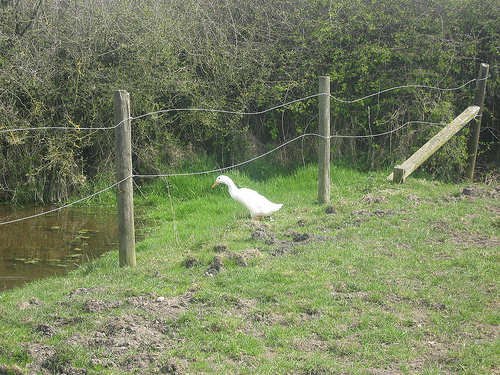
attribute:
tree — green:
[311, 7, 385, 98]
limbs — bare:
[73, 25, 151, 78]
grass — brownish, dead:
[74, 300, 194, 372]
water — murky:
[2, 204, 148, 295]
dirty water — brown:
[0, 194, 135, 294]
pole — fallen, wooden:
[387, 102, 479, 177]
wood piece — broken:
[384, 99, 481, 186]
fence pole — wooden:
[102, 81, 145, 272]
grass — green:
[4, 168, 489, 366]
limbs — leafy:
[279, 3, 399, 168]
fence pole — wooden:
[112, 88, 138, 266]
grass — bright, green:
[3, 157, 499, 373]